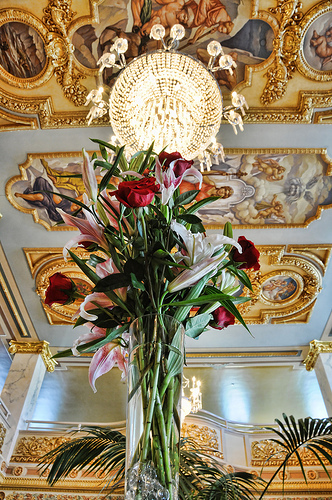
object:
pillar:
[0, 336, 58, 488]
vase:
[124, 312, 187, 499]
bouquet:
[37, 137, 258, 359]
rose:
[105, 173, 166, 213]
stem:
[135, 208, 158, 300]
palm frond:
[42, 421, 130, 482]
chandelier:
[64, 27, 256, 181]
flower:
[159, 212, 243, 282]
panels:
[0, 0, 332, 334]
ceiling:
[0, 5, 332, 345]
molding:
[10, 338, 57, 372]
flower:
[46, 201, 111, 259]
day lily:
[159, 150, 215, 210]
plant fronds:
[268, 413, 332, 484]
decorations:
[261, 61, 288, 105]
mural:
[43, 163, 316, 232]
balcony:
[14, 417, 327, 494]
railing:
[27, 417, 130, 428]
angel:
[251, 153, 287, 187]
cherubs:
[253, 192, 285, 220]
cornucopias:
[40, 5, 82, 115]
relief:
[0, 5, 331, 125]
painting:
[3, 24, 48, 79]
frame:
[27, 74, 52, 88]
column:
[1, 352, 41, 475]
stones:
[127, 458, 169, 499]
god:
[282, 174, 320, 214]